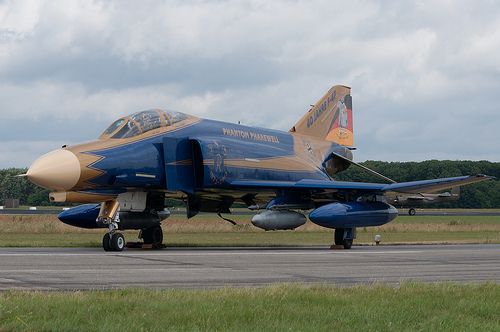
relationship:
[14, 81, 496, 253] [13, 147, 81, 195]
fighter jet has nose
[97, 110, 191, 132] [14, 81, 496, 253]
cockpit window of fighter jet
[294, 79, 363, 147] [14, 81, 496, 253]
tail of fighter jet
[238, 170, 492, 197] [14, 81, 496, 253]
left wing of fighter jet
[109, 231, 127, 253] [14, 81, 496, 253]
front wheel of fighter jet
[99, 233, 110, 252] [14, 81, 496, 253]
front wheel of fighter jet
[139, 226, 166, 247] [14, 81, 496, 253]
right bach wheel of fighter jet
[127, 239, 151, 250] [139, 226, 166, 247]
chocks near right bach wheel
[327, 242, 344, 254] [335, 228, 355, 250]
chocks near left back wheel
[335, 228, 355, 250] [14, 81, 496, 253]
left back wheel of fighter jet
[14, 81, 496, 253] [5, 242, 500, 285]
fighter jet on runway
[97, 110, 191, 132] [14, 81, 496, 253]
cockpit window on fighter jet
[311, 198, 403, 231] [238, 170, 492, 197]
engine under left wing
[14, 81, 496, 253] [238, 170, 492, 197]
fighter jet has left wing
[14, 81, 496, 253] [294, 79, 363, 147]
fighter jet has tail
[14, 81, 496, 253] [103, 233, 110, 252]
fighter jet has front wheel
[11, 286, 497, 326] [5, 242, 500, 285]
grass in front of runway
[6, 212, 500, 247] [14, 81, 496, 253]
grass behind fighter jet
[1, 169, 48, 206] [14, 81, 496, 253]
trees behind fighter jet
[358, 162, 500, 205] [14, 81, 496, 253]
trees behind fighter jet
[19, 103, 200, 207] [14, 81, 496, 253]
front part of fighter jet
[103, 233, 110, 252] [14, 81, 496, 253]
front wheel of fighter jet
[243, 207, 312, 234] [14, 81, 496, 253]
rocket on fighter jet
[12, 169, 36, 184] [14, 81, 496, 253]
sharpe edge of fighter jet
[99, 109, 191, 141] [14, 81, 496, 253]
cockpit window of fighter jet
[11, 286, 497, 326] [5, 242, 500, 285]
grass near runway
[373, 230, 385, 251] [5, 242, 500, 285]
object on runway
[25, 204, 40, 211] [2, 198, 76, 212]
post on grass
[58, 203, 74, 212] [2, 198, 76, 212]
post on grass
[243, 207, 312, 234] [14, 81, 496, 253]
rocket under fighter jet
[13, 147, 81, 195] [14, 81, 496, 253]
nose of fighter jet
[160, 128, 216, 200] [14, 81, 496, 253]
open door on fighter jet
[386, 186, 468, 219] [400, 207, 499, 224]
military plane on tarmac